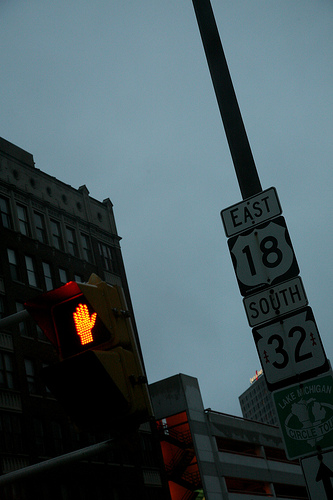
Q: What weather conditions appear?
A: It is overcast.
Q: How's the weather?
A: It is overcast.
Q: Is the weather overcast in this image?
A: Yes, it is overcast.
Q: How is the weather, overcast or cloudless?
A: It is overcast.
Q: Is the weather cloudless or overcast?
A: It is overcast.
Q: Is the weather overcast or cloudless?
A: It is overcast.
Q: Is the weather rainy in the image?
A: No, it is overcast.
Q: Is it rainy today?
A: No, it is overcast.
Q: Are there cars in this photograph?
A: No, there are no cars.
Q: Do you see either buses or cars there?
A: No, there are no cars or buses.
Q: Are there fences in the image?
A: No, there are no fences.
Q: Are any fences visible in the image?
A: No, there are no fences.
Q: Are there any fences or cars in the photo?
A: No, there are no fences or cars.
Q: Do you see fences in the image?
A: No, there are no fences.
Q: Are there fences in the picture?
A: No, there are no fences.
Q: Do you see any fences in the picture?
A: No, there are no fences.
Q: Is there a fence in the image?
A: No, there are no fences.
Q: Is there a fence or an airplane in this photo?
A: No, there are no fences or airplanes.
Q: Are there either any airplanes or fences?
A: No, there are no fences or airplanes.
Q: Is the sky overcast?
A: Yes, the sky is overcast.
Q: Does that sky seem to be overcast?
A: Yes, the sky is overcast.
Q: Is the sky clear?
A: No, the sky is overcast.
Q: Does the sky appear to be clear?
A: No, the sky is overcast.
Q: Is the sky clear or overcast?
A: The sky is overcast.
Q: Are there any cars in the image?
A: No, there are no cars.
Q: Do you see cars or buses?
A: No, there are no cars or buses.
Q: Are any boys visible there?
A: No, there are no boys.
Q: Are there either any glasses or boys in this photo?
A: No, there are no boys or glasses.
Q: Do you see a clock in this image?
A: No, there are no clocks.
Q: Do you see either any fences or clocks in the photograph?
A: No, there are no clocks or fences.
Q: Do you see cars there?
A: No, there are no cars.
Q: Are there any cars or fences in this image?
A: No, there are no cars or fences.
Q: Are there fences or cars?
A: No, there are no cars or fences.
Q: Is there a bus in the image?
A: No, there are no buses.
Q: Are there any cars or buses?
A: No, there are no buses or cars.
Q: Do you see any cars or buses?
A: No, there are no buses or cars.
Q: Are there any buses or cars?
A: No, there are no buses or cars.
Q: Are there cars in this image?
A: No, there are no cars.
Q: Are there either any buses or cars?
A: No, there are no cars or buses.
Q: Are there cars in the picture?
A: No, there are no cars.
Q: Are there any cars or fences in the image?
A: No, there are no cars or fences.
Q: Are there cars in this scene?
A: No, there are no cars.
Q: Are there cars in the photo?
A: No, there are no cars.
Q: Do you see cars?
A: No, there are no cars.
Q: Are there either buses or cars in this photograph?
A: No, there are no cars or buses.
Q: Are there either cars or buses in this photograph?
A: No, there are no cars or buses.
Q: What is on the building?
A: The sign is on the building.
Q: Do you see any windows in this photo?
A: Yes, there is a window.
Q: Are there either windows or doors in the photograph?
A: Yes, there is a window.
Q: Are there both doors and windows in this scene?
A: No, there is a window but no doors.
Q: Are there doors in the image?
A: No, there are no doors.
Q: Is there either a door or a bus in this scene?
A: No, there are no doors or buses.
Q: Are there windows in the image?
A: Yes, there is a window.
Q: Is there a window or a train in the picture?
A: Yes, there is a window.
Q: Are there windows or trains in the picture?
A: Yes, there is a window.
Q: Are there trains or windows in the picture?
A: Yes, there is a window.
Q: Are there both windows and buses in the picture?
A: No, there is a window but no buses.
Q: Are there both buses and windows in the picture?
A: No, there is a window but no buses.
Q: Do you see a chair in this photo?
A: No, there are no chairs.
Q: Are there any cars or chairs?
A: No, there are no chairs or cars.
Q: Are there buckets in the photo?
A: No, there are no buckets.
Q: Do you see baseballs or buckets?
A: No, there are no buckets or baseballs.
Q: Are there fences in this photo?
A: No, there are no fences.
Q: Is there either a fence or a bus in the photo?
A: No, there are no fences or buses.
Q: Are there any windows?
A: Yes, there is a window.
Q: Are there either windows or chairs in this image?
A: Yes, there is a window.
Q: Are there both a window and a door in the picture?
A: No, there is a window but no doors.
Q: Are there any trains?
A: No, there are no trains.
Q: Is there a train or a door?
A: No, there are no trains or doors.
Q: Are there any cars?
A: No, there are no cars.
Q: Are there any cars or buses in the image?
A: No, there are no cars or buses.